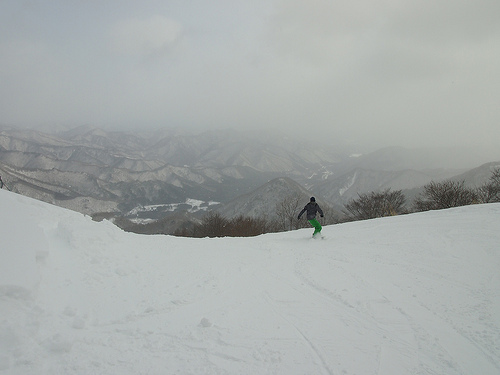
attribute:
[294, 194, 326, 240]
man — snowboarding, skiing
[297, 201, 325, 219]
jacket — gray, grey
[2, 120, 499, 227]
mountains — in the distance, gray, large, brown, snowy, in background, in the background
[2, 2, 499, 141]
sky — foggy, hazy, cloudy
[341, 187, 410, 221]
trees — bare, short, brown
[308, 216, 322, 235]
pants — green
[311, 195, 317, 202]
hat — black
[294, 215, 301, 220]
gloves — black